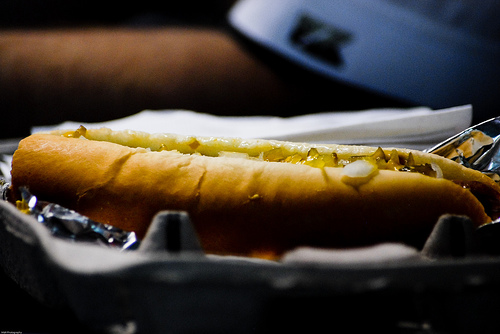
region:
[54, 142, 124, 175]
Golden surface of a bun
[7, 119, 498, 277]
A hotdog sitting on a metallic wrapper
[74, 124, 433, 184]
Grilled onions on top of a hotdog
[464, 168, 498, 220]
Tip of a hotdog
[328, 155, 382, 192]
Onion on top of a bun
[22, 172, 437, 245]
Shadow on the side of a bun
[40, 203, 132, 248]
Metallic wrapper near a hotdog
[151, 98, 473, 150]
White paper product near a hotdog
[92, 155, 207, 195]
Wrinkles in the crust of a bun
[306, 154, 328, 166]
Relish on a hotdog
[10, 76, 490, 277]
this is a hotdog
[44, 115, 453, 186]
there is relish on this hotdog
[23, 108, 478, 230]
the bun on this hotdog looks fresh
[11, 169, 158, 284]
there is some foil beneath the hotdog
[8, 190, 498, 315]
paper underneath the hotdogs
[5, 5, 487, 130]
an arm of man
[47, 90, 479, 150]
a white napkin next to the hotdog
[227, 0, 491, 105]
a white shirt on a person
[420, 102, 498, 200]
a piece of the hotdog wrapper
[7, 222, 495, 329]
a a dark part of the picture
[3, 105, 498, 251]
hotdog in bun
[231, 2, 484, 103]
sleeve with logo on it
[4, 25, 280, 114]
arm of person behind hot dog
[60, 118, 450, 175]
garnish on hotdog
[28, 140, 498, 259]
foil wrapper on hot dog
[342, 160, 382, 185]
white garnish sitting on bun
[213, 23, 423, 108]
black trim on sleeve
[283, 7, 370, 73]
black logo on sleeve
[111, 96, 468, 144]
napkins behind hot dog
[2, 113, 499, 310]
hot dog in wrapper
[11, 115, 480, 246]
Hot dog sitting on a plate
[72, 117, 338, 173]
Relish inside the bun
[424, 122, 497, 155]
Foil surrounding the food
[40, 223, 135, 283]
Silver plate under the food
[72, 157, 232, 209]
Wrinkle in the bun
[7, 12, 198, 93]
Brown chair in the background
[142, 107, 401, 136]
White napkins in a stack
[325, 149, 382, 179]
Onion on the bun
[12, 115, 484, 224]
The bun is brown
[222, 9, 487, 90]
Blue plastic in background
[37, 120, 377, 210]
this is a hot dog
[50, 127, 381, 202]
the hot dog is yummy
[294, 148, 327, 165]
the hot dog is creamy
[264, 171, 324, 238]
the ban is brown in color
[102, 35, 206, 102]
this is a hand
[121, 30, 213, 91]
the hand is brown in color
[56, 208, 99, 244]
this is a polythene paper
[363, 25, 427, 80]
this is a tin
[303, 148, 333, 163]
the cream is yellow in color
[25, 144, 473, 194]
the hot dog is long